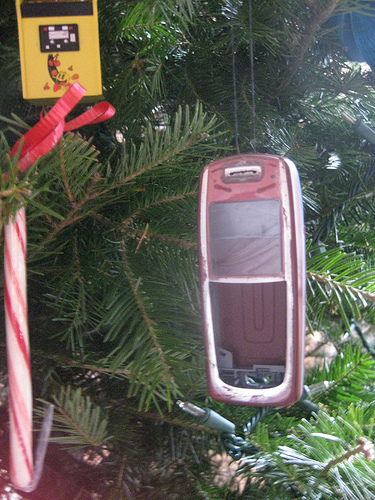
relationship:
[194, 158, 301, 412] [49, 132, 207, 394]
phone in tree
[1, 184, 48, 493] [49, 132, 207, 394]
candy in tree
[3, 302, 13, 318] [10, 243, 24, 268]
red and white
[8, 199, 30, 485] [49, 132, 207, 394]
cane in tree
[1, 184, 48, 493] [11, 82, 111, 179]
candy with ribbon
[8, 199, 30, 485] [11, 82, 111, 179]
cane with ribbon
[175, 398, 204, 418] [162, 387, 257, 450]
white christmas light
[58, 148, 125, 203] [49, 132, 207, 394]
pine christmas tree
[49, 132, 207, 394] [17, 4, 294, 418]
tree with decorations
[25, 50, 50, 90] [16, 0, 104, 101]
yellow hanging object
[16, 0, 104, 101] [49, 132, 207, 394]
object in tree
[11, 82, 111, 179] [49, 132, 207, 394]
ribbon in tree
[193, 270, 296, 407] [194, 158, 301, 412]
broken red phone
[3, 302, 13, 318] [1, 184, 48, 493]
red peppermint stick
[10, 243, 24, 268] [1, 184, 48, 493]
white peppermint stick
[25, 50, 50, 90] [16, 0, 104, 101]
yellow pacman ornament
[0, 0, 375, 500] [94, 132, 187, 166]
evergreen pine needles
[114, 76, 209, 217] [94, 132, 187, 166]
branches with needles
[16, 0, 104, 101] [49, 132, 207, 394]
ornament on tree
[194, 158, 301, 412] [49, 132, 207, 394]
ornament on tree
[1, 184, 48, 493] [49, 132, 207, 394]
ornament on tree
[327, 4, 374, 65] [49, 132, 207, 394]
ornament on tree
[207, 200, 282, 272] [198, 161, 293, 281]
clear phone screen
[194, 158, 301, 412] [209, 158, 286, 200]
phone's ear piece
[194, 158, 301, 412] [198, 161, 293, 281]
phone with screen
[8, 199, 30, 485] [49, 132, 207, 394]
cane on tree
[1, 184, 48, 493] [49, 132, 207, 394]
candy on tree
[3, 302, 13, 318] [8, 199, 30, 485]
red candy cane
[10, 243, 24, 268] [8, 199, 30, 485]
white candy cane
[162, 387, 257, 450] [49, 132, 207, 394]
light on tree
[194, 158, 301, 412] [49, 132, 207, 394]
electronic on tree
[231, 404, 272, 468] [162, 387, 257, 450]
cord for lights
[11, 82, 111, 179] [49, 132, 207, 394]
ribbon on tree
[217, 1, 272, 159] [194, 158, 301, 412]
strands holding phone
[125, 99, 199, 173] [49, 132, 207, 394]
twig of tree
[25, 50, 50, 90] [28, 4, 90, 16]
yellow and black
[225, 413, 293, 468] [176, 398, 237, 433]
wires to light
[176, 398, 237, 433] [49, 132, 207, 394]
light in tree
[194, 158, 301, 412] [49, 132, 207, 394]
phone on tree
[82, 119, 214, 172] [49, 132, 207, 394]
limb of tree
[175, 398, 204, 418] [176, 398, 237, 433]
clear light light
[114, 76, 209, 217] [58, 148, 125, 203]
branches of pine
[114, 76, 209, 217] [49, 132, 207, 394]
branches of tree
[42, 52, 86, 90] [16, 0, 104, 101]
pac-man christmas ornament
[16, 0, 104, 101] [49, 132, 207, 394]
ornament in tree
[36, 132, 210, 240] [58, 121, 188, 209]
limb of evergreen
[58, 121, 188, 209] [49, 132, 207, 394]
evergreen christmas tree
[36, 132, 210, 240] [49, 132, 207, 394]
limb of tree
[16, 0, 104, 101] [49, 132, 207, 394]
toy in tree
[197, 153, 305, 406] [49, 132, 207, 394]
phone in tree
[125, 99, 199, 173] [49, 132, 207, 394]
leaflets of tree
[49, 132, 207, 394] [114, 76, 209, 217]
tree has branches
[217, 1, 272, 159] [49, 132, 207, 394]
rope in tree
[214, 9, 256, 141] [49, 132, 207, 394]
rope in tree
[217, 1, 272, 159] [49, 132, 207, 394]
ropes in tree